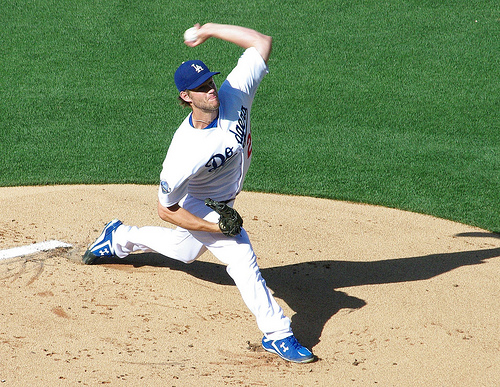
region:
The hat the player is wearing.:
[173, 62, 218, 88]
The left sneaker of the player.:
[264, 336, 319, 363]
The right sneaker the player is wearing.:
[84, 217, 126, 259]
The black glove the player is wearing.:
[206, 198, 247, 239]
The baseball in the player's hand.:
[185, 26, 195, 39]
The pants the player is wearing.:
[120, 212, 295, 347]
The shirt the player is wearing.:
[155, 49, 262, 216]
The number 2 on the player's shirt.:
[241, 133, 253, 158]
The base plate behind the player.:
[0, 235, 66, 261]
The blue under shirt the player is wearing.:
[187, 113, 218, 132]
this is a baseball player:
[81, 18, 321, 324]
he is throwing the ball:
[96, 18, 292, 334]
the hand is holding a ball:
[183, 23, 198, 43]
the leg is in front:
[226, 253, 279, 347]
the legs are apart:
[163, 238, 250, 284]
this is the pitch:
[343, 49, 468, 196]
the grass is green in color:
[353, 60, 457, 181]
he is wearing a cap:
[166, 53, 211, 91]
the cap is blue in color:
[175, 58, 208, 84]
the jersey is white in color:
[203, 128, 235, 163]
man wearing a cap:
[81, 17, 334, 377]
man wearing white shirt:
[80, 20, 345, 385]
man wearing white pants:
[86, 15, 333, 372]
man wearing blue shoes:
[86, 25, 333, 377]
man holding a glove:
[80, 25, 340, 375]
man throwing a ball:
[85, 20, 327, 370]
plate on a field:
[0, 221, 71, 269]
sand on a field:
[382, 271, 477, 354]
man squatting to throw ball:
[77, 19, 322, 385]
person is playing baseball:
[81, 20, 318, 361]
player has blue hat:
[171, 58, 219, 90]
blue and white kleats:
[79, 215, 312, 362]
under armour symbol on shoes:
[97, 245, 290, 352]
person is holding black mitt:
[204, 196, 242, 235]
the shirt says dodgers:
[198, 105, 252, 171]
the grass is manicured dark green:
[1, 0, 499, 230]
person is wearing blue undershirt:
[187, 109, 222, 129]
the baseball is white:
[181, 25, 200, 42]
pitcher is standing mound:
[0, 183, 497, 385]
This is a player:
[190, 90, 331, 332]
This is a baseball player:
[150, 66, 307, 310]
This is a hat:
[150, 38, 293, 193]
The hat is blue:
[131, 21, 303, 180]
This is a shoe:
[75, 196, 157, 267]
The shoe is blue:
[90, 203, 239, 315]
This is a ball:
[168, 33, 260, 70]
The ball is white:
[177, 22, 308, 196]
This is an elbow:
[229, 22, 278, 63]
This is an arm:
[204, 8, 256, 66]